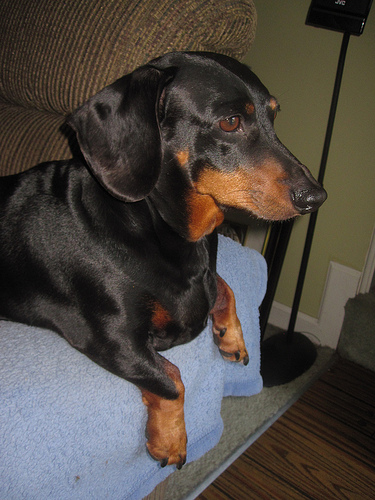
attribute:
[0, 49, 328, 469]
dog — black, brown, black ad brow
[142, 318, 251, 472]
paws — brown, black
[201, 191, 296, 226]
mouth — brown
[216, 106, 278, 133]
eyes — red, amber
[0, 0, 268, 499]
couch — brow, plaid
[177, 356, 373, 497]
floor — brown, wooden, smooth, wood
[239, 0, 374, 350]
wall — green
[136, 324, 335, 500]
carpet — grey, white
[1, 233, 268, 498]
blanket — blue, nice, fluffy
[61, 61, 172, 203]
ear — floppy, large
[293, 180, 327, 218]
nose — black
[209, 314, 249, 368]
paw — brow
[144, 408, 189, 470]
paw — brow